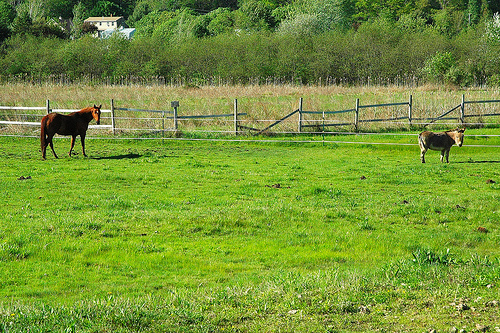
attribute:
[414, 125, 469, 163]
donkey — brown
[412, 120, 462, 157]
donkey — grey, brown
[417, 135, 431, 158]
tail — grey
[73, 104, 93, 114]
mane — brown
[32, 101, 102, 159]
horse — brown, large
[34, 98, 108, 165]
horse — brown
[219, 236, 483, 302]
grass — pasture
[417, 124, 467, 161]
horse — small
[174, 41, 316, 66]
leaves — green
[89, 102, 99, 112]
ear — brown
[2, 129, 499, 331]
pasture — grass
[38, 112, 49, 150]
tail — brown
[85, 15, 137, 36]
house — white, distant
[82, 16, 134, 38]
house — white and tan